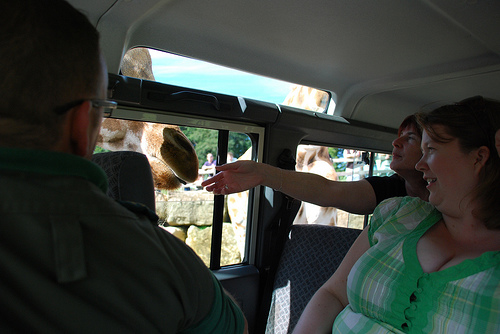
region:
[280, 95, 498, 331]
Woman sitting in the vehicle.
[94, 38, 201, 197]
Giraffe at the window.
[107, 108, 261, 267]
Window in the vehicle.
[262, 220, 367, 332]
Seat in the vehicle.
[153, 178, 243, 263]
rock outside the vehicle.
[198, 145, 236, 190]
People outside the vehicle.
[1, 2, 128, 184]
Glasses on the man.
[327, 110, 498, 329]
Green and white colors on the shirt.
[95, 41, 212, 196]
Brown spots on the giraffe.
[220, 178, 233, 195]
ring on the finger.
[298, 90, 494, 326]
this is a woman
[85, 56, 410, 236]
a person petting a giraffe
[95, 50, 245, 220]
this is a giraffe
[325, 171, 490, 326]
woman wearing a plaid shirt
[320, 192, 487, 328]
green and white plaid design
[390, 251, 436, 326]
green buttons on shirt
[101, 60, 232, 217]
giraffes mouth in window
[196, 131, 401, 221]
woman has arm extended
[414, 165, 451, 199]
woman is smiling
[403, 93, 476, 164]
woman has bangs on face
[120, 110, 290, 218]
The giraffe in the window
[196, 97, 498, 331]
The tourists int he van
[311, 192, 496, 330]
The woman is wearing a green and white shirt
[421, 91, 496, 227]
The woman has brown hair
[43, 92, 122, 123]
The man is wearing glasses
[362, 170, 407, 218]
The woman is wearing a black shirt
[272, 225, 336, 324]
The seat is the color blue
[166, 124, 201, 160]
The nose of the giraffe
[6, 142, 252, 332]
The man is wearing a green shirt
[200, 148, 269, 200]
The hand of the woman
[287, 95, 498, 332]
Woman wearing a white and green shirt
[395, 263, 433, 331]
Buttons barely holding on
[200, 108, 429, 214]
Woman reaching her arm towards a giraffe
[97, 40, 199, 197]
Giraffe head poking into a vehicle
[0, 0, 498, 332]
Three people in a vehicle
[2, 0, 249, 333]
Man wearing a dark shirt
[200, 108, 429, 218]
Woman wearing a black shirt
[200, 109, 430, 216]
Woman reaching for a giraffe's mouth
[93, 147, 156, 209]
Gray cushioned seat of a vehicle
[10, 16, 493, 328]
Some people are sitting in a train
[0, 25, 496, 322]
Some people are watching the giraffes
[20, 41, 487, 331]
Some people are petting a giraffe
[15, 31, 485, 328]
The people can see a giraffe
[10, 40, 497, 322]
A giraffe is getting some attention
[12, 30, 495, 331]
The giraffes are out in the daytime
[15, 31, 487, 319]
The giraffes are having a great time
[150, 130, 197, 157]
nose is apart of giraffe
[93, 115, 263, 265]
window is apart of the car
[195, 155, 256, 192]
hand is out the window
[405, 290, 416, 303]
button is apart of shirt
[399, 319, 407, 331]
button is apart of ladies shirt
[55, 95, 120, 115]
glasses are on the mans head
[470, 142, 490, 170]
ear is apart of ladies face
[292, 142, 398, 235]
window is apart of the car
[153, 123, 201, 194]
nose of a giraffe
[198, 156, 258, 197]
hand near a giraffe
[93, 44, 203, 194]
head of a giraffe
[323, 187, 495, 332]
green and white colored shirt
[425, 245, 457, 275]
cleavage of a woman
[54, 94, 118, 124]
glasses on a man's face